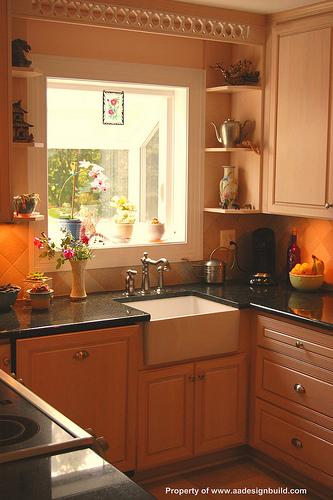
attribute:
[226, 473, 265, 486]
floor — wood, brown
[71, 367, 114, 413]
cabinets — wood, brown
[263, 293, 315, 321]
countertop — black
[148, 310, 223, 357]
sink — white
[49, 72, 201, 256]
window — trimmed in white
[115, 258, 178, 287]
faucet — gray, metal, silver, chrome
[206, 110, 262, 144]
watering can — silver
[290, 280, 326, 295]
bowl — blue, green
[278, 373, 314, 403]
knobs — gold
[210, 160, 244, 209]
vase — decorative, white blue, pink, colorful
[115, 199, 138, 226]
plant — potted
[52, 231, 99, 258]
flowers — pink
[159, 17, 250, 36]
trim — decorative, white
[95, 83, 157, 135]
decoration — stained glass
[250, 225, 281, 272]
coffee maker — black, silver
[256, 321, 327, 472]
drawers — 3, brown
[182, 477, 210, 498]
tile — gray, on floor, white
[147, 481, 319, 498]
watermark — www.aadesignbuild.co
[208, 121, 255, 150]
teapot — gray, metal, silver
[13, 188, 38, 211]
plant — dying